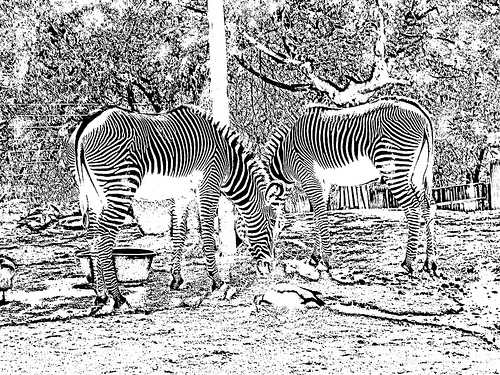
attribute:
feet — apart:
[168, 200, 224, 293]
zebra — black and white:
[232, 101, 430, 274]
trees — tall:
[292, 16, 438, 125]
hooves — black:
[84, 287, 136, 319]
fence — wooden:
[429, 179, 489, 211]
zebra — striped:
[197, 109, 359, 254]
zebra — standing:
[60, 89, 290, 314]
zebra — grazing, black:
[65, 97, 282, 310]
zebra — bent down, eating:
[228, 57, 479, 282]